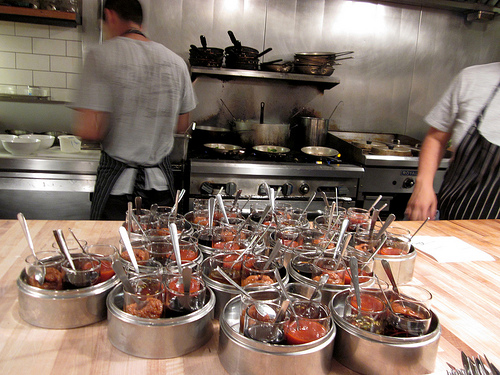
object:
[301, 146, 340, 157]
pan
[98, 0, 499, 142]
oven wall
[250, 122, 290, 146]
pot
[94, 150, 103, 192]
edge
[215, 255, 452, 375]
sufuria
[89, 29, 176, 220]
apron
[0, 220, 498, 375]
table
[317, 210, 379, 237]
pot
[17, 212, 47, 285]
spoon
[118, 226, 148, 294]
spoon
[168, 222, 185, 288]
spoon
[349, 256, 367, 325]
spoon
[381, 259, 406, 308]
spoon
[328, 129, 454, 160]
flattop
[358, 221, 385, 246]
ground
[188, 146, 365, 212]
stove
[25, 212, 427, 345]
dishes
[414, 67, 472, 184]
arm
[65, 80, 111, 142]
arm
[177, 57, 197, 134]
arm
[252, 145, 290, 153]
pan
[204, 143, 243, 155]
pan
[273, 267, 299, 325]
handle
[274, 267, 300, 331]
spoon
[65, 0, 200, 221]
guy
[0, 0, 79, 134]
wall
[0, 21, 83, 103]
bricks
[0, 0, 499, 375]
kitchen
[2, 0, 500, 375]
camera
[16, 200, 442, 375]
containers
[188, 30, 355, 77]
pots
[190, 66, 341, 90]
shelf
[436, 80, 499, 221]
apron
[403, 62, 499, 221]
man